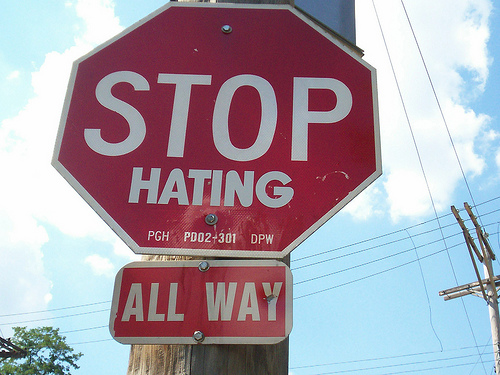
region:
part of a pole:
[274, 335, 281, 372]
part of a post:
[134, 352, 151, 371]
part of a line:
[396, 243, 406, 256]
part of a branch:
[29, 342, 51, 354]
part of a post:
[212, 165, 247, 200]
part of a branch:
[51, 342, 63, 357]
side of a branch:
[40, 338, 54, 354]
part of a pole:
[458, 229, 488, 264]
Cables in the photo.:
[357, 235, 388, 276]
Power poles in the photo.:
[475, 255, 497, 304]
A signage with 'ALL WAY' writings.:
[107, 265, 292, 343]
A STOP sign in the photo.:
[50, 1, 384, 255]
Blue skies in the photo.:
[352, 296, 404, 354]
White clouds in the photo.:
[15, 170, 50, 223]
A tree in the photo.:
[27, 336, 68, 372]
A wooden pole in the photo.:
[155, 352, 236, 374]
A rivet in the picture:
[193, 331, 204, 341]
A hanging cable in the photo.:
[412, 272, 444, 337]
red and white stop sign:
[37, 5, 403, 267]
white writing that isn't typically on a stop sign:
[117, 161, 304, 222]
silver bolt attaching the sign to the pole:
[192, 327, 207, 344]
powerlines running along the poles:
[5, 3, 495, 373]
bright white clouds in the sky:
[1, 1, 498, 374]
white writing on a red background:
[121, 283, 283, 327]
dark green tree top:
[3, 322, 79, 372]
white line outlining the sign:
[52, 1, 372, 262]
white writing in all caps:
[79, 66, 358, 164]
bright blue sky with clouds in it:
[3, 1, 499, 374]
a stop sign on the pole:
[45, 4, 372, 245]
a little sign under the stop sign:
[98, 253, 300, 354]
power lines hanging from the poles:
[1, 196, 496, 363]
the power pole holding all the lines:
[429, 199, 499, 371]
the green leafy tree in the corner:
[0, 326, 82, 369]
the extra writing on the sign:
[123, 164, 298, 222]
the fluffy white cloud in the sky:
[358, 3, 484, 206]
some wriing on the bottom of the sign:
[136, 225, 281, 250]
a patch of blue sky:
[320, 280, 472, 347]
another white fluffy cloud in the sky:
[5, 16, 79, 262]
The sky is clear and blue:
[326, 248, 487, 374]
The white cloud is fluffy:
[367, 8, 457, 203]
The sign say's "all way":
[103, 260, 297, 355]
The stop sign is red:
[48, 3, 385, 261]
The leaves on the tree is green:
[9, 325, 66, 372]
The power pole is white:
[440, 171, 498, 372]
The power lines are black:
[323, 158, 495, 297]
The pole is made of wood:
[123, 343, 295, 373]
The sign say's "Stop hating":
[91, 73, 351, 205]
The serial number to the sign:
[141, 225, 278, 247]